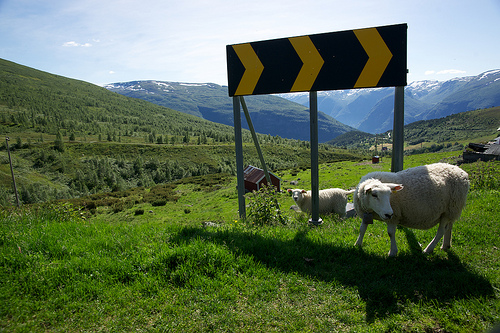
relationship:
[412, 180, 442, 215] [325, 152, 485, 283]
fur on sheep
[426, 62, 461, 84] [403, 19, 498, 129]
cloud in sky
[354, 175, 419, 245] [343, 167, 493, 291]
head of sheep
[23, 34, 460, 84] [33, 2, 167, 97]
cloud in sky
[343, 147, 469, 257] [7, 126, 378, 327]
sheep in a field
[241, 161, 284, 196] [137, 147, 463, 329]
house in field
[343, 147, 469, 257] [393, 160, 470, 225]
sheep has wool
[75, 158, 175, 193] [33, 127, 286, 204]
trees in valley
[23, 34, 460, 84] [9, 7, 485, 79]
cloud in sky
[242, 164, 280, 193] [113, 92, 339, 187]
building in distance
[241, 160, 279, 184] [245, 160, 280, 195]
roof on building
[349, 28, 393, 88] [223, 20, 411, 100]
arrows on sign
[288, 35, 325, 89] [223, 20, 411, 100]
arrows on sign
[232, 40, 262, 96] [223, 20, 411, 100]
arrows on sign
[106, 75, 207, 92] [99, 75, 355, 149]
snow on mountains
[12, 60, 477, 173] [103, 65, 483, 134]
mountain in distance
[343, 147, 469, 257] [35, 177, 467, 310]
sheep on field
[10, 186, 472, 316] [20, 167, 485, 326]
grass on field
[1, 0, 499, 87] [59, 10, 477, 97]
sky in background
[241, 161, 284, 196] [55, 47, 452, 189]
house in background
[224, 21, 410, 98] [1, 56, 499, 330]
sign in field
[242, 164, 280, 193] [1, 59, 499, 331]
building lower down hill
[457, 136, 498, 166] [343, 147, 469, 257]
building behind sheep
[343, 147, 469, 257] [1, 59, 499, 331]
sheep standing on grass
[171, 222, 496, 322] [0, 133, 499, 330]
shadow on ground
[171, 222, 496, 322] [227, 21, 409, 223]
shadow from sign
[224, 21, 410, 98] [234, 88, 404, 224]
sign on post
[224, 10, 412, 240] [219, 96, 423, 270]
sign on posts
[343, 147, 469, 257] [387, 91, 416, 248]
sheep standing post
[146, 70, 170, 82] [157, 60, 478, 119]
snow covered mountain